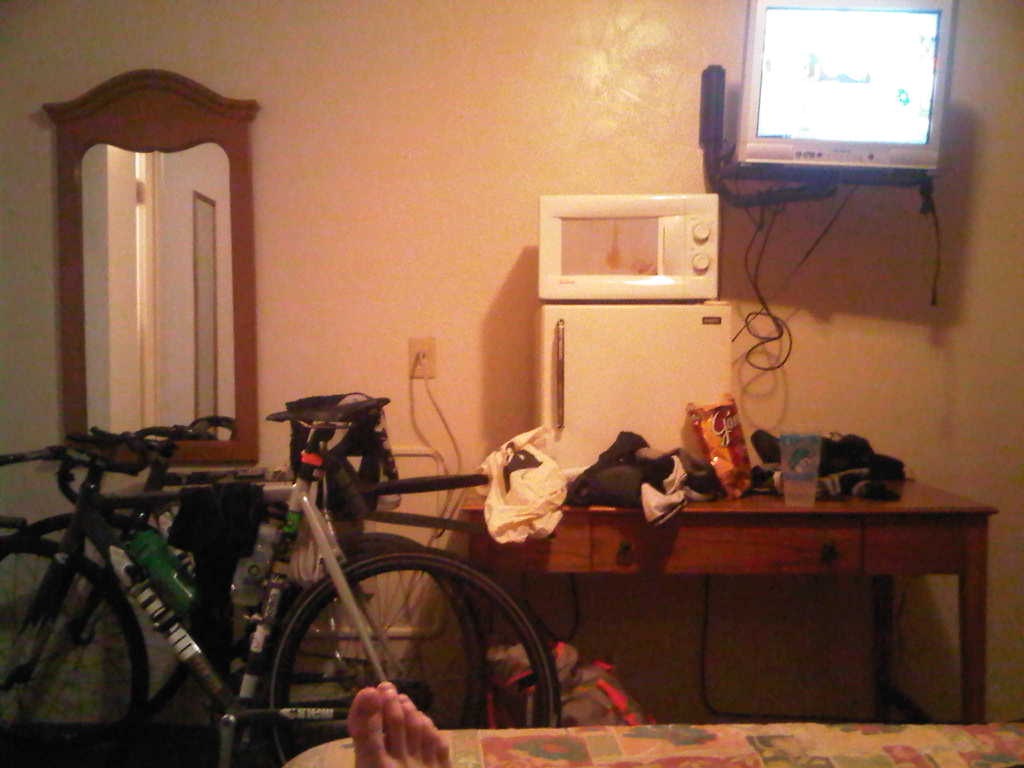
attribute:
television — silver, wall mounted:
[715, 5, 966, 189]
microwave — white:
[535, 188, 723, 306]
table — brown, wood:
[456, 469, 1001, 726]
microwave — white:
[536, 184, 726, 298]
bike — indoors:
[4, 386, 567, 766]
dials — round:
[689, 219, 715, 278]